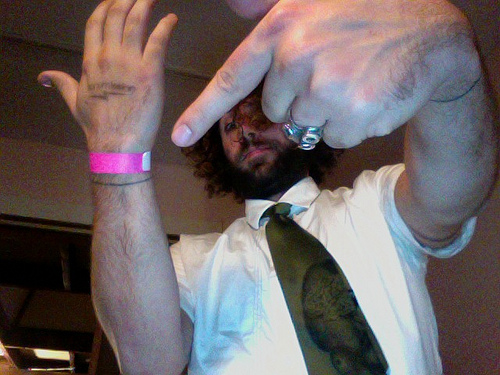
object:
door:
[0, 211, 181, 374]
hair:
[413, 13, 486, 123]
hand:
[170, 0, 472, 149]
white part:
[142, 151, 152, 172]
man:
[36, 0, 499, 373]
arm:
[90, 172, 195, 374]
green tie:
[261, 202, 394, 374]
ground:
[244, 47, 343, 93]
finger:
[292, 96, 327, 128]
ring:
[282, 107, 328, 151]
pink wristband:
[87, 150, 152, 175]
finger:
[171, 9, 279, 147]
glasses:
[218, 108, 271, 140]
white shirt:
[169, 163, 478, 375]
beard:
[229, 152, 285, 199]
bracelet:
[88, 151, 152, 174]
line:
[89, 176, 152, 186]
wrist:
[88, 152, 157, 199]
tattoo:
[88, 81, 135, 102]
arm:
[379, 71, 500, 247]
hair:
[180, 85, 344, 205]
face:
[220, 93, 291, 180]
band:
[87, 151, 156, 171]